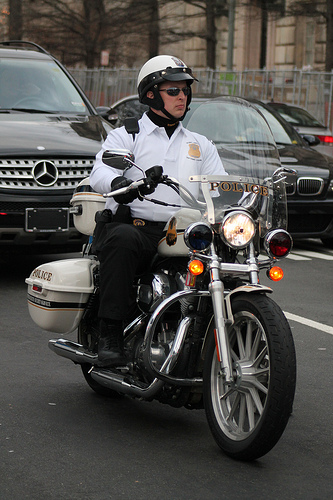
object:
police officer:
[88, 54, 245, 366]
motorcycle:
[24, 116, 297, 461]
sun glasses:
[156, 86, 192, 98]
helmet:
[136, 52, 199, 103]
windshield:
[178, 95, 288, 228]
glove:
[111, 175, 138, 206]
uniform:
[88, 109, 230, 330]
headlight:
[219, 210, 257, 250]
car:
[108, 92, 288, 249]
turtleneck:
[144, 108, 180, 127]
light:
[267, 266, 285, 282]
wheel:
[204, 292, 297, 464]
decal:
[207, 182, 265, 196]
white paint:
[282, 309, 333, 335]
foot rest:
[91, 362, 149, 394]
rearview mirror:
[102, 149, 134, 171]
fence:
[63, 67, 333, 127]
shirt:
[88, 108, 228, 230]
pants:
[92, 205, 167, 323]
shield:
[187, 141, 202, 159]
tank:
[24, 256, 100, 335]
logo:
[32, 158, 59, 188]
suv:
[0, 39, 118, 252]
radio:
[123, 117, 141, 142]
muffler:
[47, 338, 96, 366]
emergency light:
[265, 228, 294, 260]